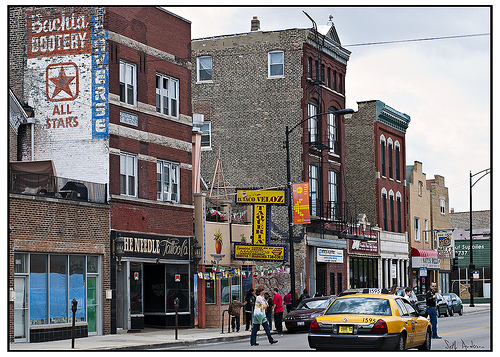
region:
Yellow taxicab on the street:
[308, 286, 433, 346]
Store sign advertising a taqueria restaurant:
[253, 203, 268, 244]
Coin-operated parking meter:
[68, 298, 78, 348]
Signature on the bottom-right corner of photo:
[442, 337, 491, 351]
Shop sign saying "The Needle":
[115, 233, 162, 254]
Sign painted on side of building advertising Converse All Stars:
[27, 8, 108, 138]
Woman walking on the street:
[251, 284, 278, 345]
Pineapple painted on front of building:
[209, 227, 226, 255]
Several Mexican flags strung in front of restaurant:
[204, 261, 291, 277]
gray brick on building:
[216, 56, 231, 72]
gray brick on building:
[246, 60, 267, 88]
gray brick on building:
[207, 85, 242, 115]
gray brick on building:
[261, 87, 293, 119]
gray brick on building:
[205, 95, 225, 115]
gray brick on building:
[216, 125, 233, 145]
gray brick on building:
[239, 118, 259, 138]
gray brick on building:
[264, 116, 296, 158]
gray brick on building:
[221, 124, 253, 187]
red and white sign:
[27, 0, 112, 141]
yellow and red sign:
[229, 183, 284, 254]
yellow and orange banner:
[287, 176, 322, 228]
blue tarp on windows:
[23, 258, 71, 315]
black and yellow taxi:
[327, 289, 399, 352]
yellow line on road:
[432, 318, 478, 350]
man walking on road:
[420, 285, 440, 331]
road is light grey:
[443, 313, 490, 346]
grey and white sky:
[402, 11, 471, 131]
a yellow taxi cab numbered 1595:
[309, 290, 433, 347]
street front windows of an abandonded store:
[10, 246, 108, 342]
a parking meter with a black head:
[68, 296, 80, 346]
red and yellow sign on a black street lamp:
[276, 103, 358, 305]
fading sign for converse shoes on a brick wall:
[21, 7, 111, 147]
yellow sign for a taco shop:
[229, 182, 289, 268]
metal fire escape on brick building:
[300, 26, 355, 296]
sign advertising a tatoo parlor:
[108, 226, 193, 266]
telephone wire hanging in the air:
[352, 17, 487, 61]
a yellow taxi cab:
[307, 286, 423, 346]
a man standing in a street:
[426, 276, 441, 339]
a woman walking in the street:
[250, 283, 272, 348]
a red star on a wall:
[49, 59, 80, 99]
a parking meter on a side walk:
[172, 295, 181, 344]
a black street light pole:
[283, 107, 353, 307]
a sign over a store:
[114, 236, 189, 251]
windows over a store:
[112, 153, 187, 203]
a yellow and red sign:
[232, 187, 284, 260]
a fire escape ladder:
[311, 203, 373, 242]